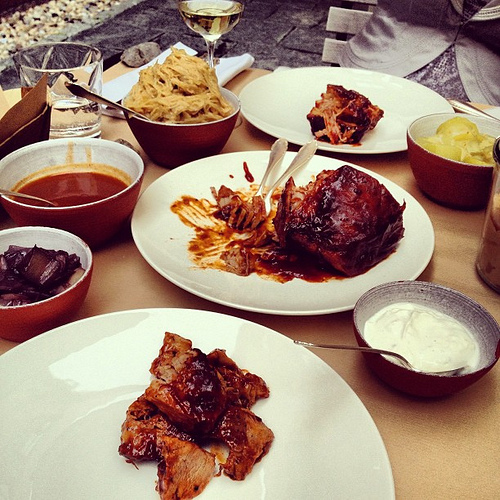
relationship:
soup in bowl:
[11, 143, 132, 207] [0, 136, 145, 246]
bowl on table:
[0, 136, 145, 246] [3, 62, 498, 500]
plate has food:
[132, 145, 433, 317] [274, 166, 407, 287]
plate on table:
[132, 145, 433, 317] [3, 62, 498, 500]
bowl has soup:
[0, 136, 145, 246] [11, 143, 132, 207]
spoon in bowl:
[2, 187, 61, 208] [0, 136, 145, 246]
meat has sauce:
[119, 331, 276, 497] [170, 354, 226, 430]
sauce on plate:
[174, 158, 343, 284] [132, 145, 433, 317]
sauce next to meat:
[174, 158, 343, 284] [274, 166, 407, 287]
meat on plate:
[274, 166, 407, 287] [132, 145, 433, 317]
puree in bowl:
[124, 41, 234, 123] [120, 86, 240, 166]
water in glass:
[48, 96, 101, 138] [14, 43, 102, 144]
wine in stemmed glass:
[180, 0, 245, 39] [176, 2, 246, 71]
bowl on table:
[120, 86, 240, 166] [3, 62, 498, 500]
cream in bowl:
[365, 302, 481, 374] [353, 279, 499, 401]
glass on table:
[14, 43, 102, 144] [3, 62, 498, 500]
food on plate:
[274, 166, 407, 287] [132, 145, 433, 317]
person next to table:
[339, 0, 499, 107] [3, 62, 498, 500]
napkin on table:
[102, 39, 256, 123] [3, 62, 498, 500]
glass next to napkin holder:
[14, 43, 102, 144] [0, 71, 53, 158]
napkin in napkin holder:
[0, 74, 50, 146] [0, 71, 53, 158]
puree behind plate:
[124, 41, 234, 123] [132, 145, 433, 317]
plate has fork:
[132, 145, 433, 317] [229, 141, 320, 230]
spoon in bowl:
[292, 338, 467, 377] [353, 279, 499, 401]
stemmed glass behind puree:
[176, 2, 246, 71] [124, 41, 234, 123]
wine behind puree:
[180, 0, 245, 39] [124, 41, 234, 123]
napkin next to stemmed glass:
[102, 39, 256, 123] [176, 2, 246, 71]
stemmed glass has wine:
[176, 2, 246, 71] [180, 0, 245, 39]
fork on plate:
[229, 141, 320, 230] [132, 145, 433, 317]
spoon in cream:
[292, 338, 467, 377] [365, 302, 481, 374]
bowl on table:
[353, 279, 499, 401] [3, 62, 498, 500]